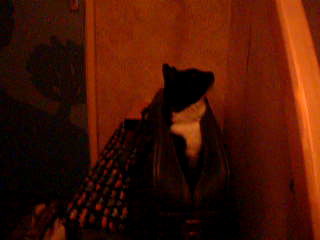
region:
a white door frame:
[82, 0, 96, 175]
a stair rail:
[270, 2, 319, 238]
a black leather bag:
[130, 93, 233, 235]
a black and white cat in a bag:
[155, 56, 217, 184]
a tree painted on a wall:
[27, 33, 87, 123]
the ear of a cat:
[158, 61, 175, 79]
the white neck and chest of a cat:
[176, 90, 208, 167]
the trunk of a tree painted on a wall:
[57, 75, 73, 117]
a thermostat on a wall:
[67, 0, 80, 12]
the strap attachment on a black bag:
[178, 218, 205, 238]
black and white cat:
[141, 54, 243, 201]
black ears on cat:
[154, 55, 181, 81]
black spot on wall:
[266, 162, 303, 205]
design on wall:
[17, 30, 89, 136]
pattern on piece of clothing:
[80, 172, 122, 222]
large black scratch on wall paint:
[233, 23, 264, 85]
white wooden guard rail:
[279, 10, 318, 130]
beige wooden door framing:
[81, 6, 99, 163]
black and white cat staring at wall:
[129, 49, 249, 204]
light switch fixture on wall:
[67, 0, 82, 15]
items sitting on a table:
[46, 57, 251, 238]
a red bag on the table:
[142, 128, 233, 238]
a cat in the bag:
[153, 59, 220, 178]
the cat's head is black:
[156, 58, 216, 113]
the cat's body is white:
[169, 97, 205, 160]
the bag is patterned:
[60, 119, 132, 234]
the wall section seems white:
[80, 0, 319, 234]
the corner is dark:
[2, 1, 318, 237]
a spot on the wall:
[241, 21, 254, 75]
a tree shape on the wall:
[20, 33, 91, 128]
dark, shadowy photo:
[13, 7, 301, 231]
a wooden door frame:
[76, 13, 103, 141]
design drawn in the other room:
[21, 20, 86, 121]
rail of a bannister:
[267, 5, 310, 39]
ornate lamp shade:
[64, 167, 128, 228]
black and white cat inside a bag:
[136, 57, 226, 211]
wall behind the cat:
[92, 0, 245, 57]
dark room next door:
[1, 4, 88, 183]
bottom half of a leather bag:
[138, 162, 228, 206]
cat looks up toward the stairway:
[104, 20, 316, 164]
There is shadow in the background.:
[28, 32, 89, 116]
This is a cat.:
[159, 59, 218, 157]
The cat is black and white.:
[133, 58, 210, 169]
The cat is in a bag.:
[126, 47, 233, 228]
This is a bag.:
[145, 167, 238, 228]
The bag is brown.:
[138, 161, 207, 235]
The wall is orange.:
[94, 24, 153, 88]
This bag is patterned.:
[73, 150, 128, 237]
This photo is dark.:
[19, 32, 301, 231]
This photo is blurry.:
[21, 44, 296, 227]